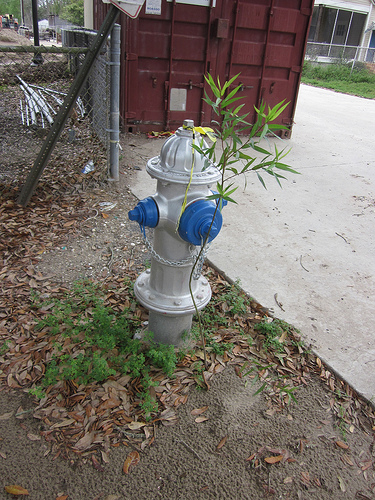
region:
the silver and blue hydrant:
[132, 116, 230, 349]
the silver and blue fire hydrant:
[124, 122, 231, 349]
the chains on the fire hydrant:
[140, 227, 210, 277]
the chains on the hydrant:
[142, 234, 208, 280]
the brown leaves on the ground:
[53, 384, 155, 457]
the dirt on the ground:
[163, 431, 220, 497]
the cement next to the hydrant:
[233, 193, 363, 298]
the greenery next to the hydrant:
[45, 296, 146, 385]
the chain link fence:
[1, 39, 139, 192]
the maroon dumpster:
[129, 8, 297, 137]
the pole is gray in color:
[105, 19, 127, 184]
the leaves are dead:
[49, 413, 127, 455]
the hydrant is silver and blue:
[120, 129, 247, 341]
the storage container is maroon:
[132, 10, 280, 113]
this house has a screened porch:
[306, 1, 369, 59]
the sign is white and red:
[98, 0, 158, 12]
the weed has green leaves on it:
[194, 67, 294, 225]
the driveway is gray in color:
[307, 108, 368, 160]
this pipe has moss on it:
[2, 35, 89, 58]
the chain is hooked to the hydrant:
[133, 205, 231, 298]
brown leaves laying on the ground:
[271, 454, 284, 458]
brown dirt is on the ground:
[197, 487, 205, 499]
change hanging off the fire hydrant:
[148, 256, 190, 266]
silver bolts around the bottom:
[173, 300, 184, 304]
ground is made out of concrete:
[314, 304, 339, 317]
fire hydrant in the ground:
[144, 178, 213, 345]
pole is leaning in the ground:
[27, 141, 52, 171]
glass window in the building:
[334, 12, 344, 60]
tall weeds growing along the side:
[185, 70, 232, 390]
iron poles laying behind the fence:
[29, 87, 60, 127]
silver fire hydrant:
[152, 115, 209, 330]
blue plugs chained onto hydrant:
[122, 195, 221, 273]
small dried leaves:
[17, 390, 127, 459]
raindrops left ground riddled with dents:
[60, 393, 291, 490]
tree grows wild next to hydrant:
[169, 66, 297, 361]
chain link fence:
[0, 20, 120, 192]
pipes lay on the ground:
[6, 69, 90, 144]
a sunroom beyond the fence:
[301, 0, 373, 89]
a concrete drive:
[211, 71, 373, 404]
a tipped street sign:
[17, 0, 147, 226]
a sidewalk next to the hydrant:
[140, 124, 373, 361]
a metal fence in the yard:
[1, 48, 115, 186]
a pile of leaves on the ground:
[60, 386, 167, 464]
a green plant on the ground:
[51, 282, 153, 396]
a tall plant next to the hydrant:
[179, 75, 293, 333]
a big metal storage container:
[105, 7, 289, 135]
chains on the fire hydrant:
[136, 219, 224, 281]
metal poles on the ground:
[6, 71, 77, 134]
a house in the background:
[316, 4, 367, 66]